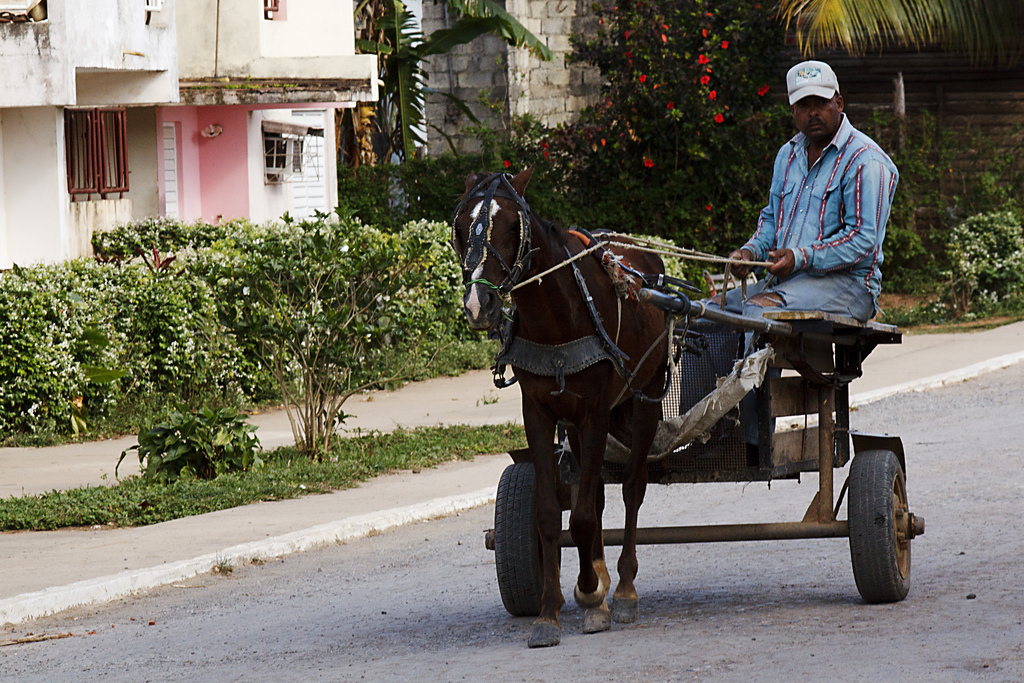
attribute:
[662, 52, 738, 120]
flowers — red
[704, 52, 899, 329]
man — driving, sitting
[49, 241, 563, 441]
bush — flowering, flowring, green, small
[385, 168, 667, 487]
horse — chestnut, small, pink, black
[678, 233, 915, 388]
jeans — blue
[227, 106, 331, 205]
air conditioner — protruding, white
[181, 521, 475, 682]
concrete — sidewalk path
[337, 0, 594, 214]
tree — banana tree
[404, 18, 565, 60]
leaf — palm, green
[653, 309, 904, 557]
cart — horsedrawn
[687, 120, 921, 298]
shirt — blue, pale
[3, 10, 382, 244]
building — white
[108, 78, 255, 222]
entry — pink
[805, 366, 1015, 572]
street — flat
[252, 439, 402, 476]
grass — short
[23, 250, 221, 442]
shrub — green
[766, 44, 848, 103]
hat — white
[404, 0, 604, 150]
wall — grey